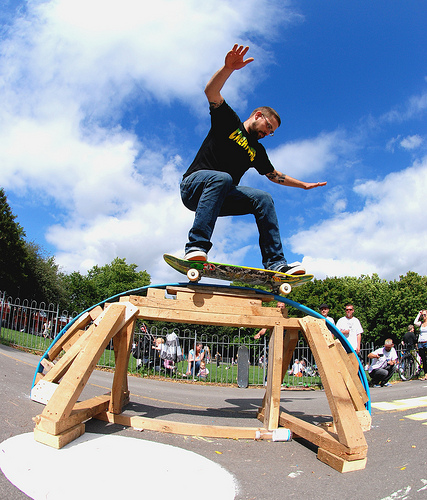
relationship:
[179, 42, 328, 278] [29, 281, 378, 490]
man skateboarding on half-circle